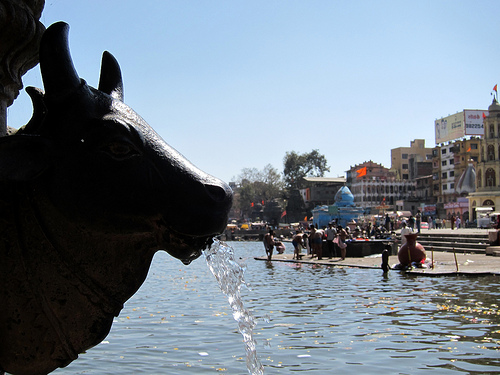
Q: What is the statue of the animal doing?
A: Spouting water.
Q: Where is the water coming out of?
A: Animal's mouth.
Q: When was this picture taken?
A: Daytime.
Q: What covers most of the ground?
A: Water.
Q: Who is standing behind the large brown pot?
A: Man in white.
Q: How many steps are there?
A: Four.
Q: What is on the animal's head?
A: Horns.